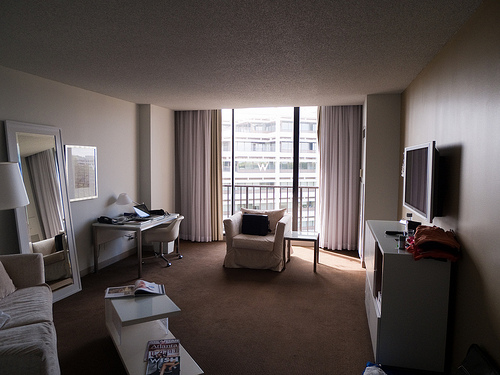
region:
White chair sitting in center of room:
[220, 204, 290, 280]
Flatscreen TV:
[397, 138, 449, 225]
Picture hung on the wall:
[62, 141, 104, 203]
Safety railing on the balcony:
[214, 179, 323, 241]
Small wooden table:
[280, 224, 330, 281]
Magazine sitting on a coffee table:
[103, 278, 170, 300]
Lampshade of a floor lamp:
[0, 153, 37, 215]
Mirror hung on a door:
[16, 130, 76, 294]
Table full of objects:
[92, 200, 184, 281]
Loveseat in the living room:
[0, 248, 63, 373]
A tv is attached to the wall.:
[391, 136, 456, 229]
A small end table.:
[276, 220, 321, 275]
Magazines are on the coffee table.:
[130, 330, 187, 374]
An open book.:
[95, 265, 170, 305]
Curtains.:
[170, 110, 220, 235]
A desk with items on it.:
[85, 200, 190, 275]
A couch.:
[0, 250, 55, 370]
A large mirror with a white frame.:
[0, 100, 75, 315]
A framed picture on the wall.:
[60, 140, 100, 200]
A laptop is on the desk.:
[126, 195, 161, 220]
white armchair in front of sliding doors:
[223, 206, 287, 271]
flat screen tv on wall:
[401, 139, 443, 226]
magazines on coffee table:
[144, 337, 181, 374]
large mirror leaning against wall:
[3, 119, 83, 302]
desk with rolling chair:
[89, 209, 183, 276]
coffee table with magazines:
[102, 286, 204, 373]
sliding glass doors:
[221, 112, 319, 240]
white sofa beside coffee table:
[1, 251, 62, 373]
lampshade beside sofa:
[0, 159, 32, 214]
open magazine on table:
[105, 277, 165, 299]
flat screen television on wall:
[392, 134, 450, 230]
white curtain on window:
[309, 103, 361, 248]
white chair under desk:
[141, 211, 195, 253]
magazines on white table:
[145, 331, 181, 373]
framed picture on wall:
[58, 136, 108, 208]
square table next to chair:
[273, 228, 325, 270]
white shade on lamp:
[4, 154, 36, 215]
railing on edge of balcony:
[272, 177, 324, 221]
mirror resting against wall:
[4, 114, 84, 229]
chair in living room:
[220, 204, 286, 269]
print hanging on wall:
[66, 141, 101, 201]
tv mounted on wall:
[375, 147, 431, 217]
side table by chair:
[283, 227, 323, 275]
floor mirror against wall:
[11, 122, 83, 297]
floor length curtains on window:
[316, 107, 356, 259]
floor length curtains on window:
[178, 112, 231, 253]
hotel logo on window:
[254, 162, 269, 172]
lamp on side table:
[110, 187, 128, 215]